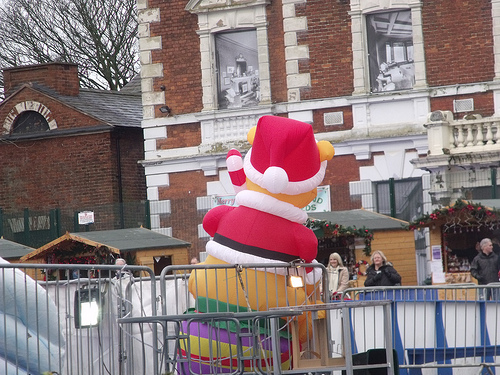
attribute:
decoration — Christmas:
[178, 111, 338, 372]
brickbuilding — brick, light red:
[135, 6, 497, 205]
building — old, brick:
[0, 62, 149, 249]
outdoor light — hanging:
[288, 262, 308, 287]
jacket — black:
[360, 265, 396, 285]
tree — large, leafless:
[0, 0, 137, 101]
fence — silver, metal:
[3, 261, 498, 367]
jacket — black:
[362, 263, 402, 292]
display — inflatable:
[175, 114, 337, 373]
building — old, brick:
[130, 1, 498, 272]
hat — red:
[242, 112, 330, 196]